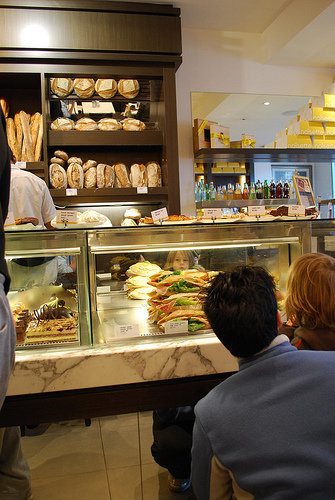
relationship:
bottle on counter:
[214, 180, 226, 202] [193, 196, 303, 210]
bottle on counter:
[233, 178, 245, 203] [193, 196, 303, 210]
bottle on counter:
[256, 178, 264, 201] [193, 196, 303, 210]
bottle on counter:
[267, 178, 279, 203] [193, 196, 303, 210]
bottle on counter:
[281, 176, 291, 203] [193, 196, 303, 210]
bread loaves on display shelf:
[48, 160, 70, 193] [42, 65, 185, 221]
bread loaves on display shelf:
[96, 163, 118, 192] [42, 65, 185, 221]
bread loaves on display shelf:
[131, 161, 150, 189] [42, 65, 185, 221]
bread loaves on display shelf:
[48, 117, 80, 132] [42, 65, 185, 221]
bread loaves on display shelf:
[116, 117, 148, 134] [42, 65, 185, 221]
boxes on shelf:
[313, 91, 334, 110] [193, 145, 335, 159]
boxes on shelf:
[290, 119, 329, 139] [193, 145, 335, 159]